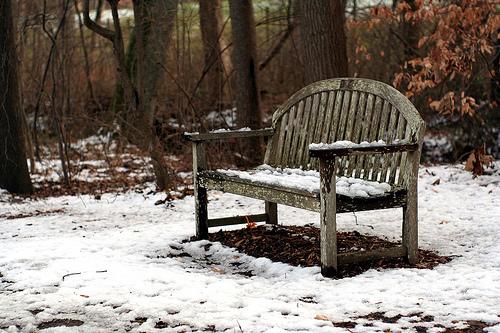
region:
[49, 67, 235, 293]
the bench is old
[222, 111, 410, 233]
the bench is old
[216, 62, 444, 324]
the bench is old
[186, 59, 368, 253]
the bench is old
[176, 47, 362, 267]
the bench is covered with snow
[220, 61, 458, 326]
the bench is covered with snow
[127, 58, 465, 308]
bench out in snow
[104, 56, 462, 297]
empty bench out in snow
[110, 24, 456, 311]
wooden bench out in snow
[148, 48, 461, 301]
old bench out in snow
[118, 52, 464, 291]
aged bench out in snow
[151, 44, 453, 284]
classic bench out in snow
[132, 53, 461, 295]
sturdy bench out in snow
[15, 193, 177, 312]
snow fallen on ground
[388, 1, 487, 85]
patch of brown leaves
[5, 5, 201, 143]
set of trees in winter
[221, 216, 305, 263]
brown leaves under a bench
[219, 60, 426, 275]
old bench with snow on seat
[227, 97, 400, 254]
wooden bench with snow on seat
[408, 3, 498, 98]
tree with brown dead leaves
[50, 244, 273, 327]
snow on the ground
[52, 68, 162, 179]
bare branches on a bush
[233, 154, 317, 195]
white snow on seat of bench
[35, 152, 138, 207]
leaves and snow on the ground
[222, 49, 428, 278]
brown wooden bench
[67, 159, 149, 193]
leaves on ground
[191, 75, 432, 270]
Bench covered in snow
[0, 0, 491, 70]
Trees and brush in wooded area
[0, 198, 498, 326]
Snow covered ground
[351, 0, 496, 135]
Leaves on a tree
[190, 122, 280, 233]
Wooden arm on the bench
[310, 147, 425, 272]
Wooden arm on the bench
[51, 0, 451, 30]
Stream running behind woods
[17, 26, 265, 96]
Leaves on trees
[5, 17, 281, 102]
Brush on the river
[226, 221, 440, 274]
Dry area from bench cover